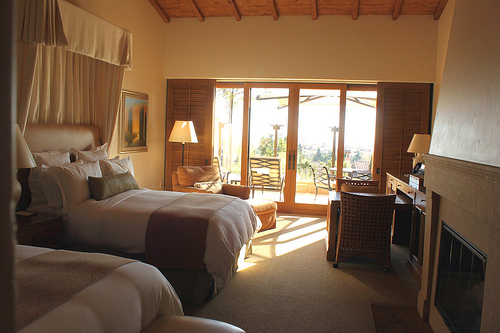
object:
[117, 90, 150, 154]
desert landscape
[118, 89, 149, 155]
hanging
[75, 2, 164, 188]
wall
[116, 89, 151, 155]
painting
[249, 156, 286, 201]
chair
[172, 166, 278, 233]
chair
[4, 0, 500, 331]
bedroom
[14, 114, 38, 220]
lamp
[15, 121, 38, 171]
lamp shade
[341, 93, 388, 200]
door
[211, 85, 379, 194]
windows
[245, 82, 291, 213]
door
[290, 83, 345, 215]
door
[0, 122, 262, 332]
beds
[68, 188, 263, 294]
cover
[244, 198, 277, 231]
ottoman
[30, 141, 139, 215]
pillows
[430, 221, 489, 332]
vent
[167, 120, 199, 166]
lamp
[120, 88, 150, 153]
picture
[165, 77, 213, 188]
door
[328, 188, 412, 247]
table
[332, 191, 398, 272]
chair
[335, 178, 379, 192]
chair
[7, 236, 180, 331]
cover